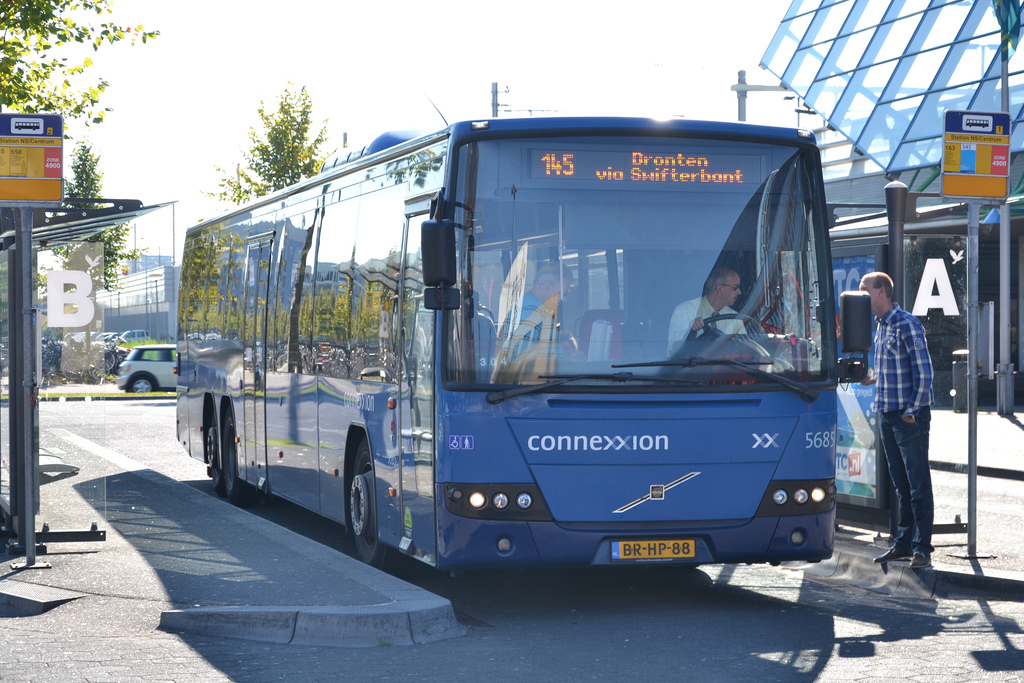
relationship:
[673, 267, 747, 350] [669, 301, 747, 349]
bus driver wearing a shirt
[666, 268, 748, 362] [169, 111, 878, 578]
bus driver sitting inside bus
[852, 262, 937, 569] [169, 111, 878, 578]
guy standing next to bus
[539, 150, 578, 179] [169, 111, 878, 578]
number lit up on bus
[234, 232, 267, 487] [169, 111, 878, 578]
door leading to bus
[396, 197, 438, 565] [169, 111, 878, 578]
door leading to bus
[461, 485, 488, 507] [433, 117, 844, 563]
light mounted on front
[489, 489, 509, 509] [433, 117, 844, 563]
light mounted on front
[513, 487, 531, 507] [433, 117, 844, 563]
light mounted on front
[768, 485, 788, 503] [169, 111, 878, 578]
light mounted on bus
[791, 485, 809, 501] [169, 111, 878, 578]
light mounted on bus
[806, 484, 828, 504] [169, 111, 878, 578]
light mounted on bus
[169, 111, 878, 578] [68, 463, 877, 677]
bus casting shadow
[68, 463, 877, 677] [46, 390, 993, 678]
shadow casted on street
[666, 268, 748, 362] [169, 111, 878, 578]
bus driver driving bus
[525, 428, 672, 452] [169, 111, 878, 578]
word printed on bus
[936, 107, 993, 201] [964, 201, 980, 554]
sign mounted on post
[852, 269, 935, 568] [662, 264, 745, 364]
guy talking to bus driver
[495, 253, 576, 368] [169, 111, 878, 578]
person standing inside bus